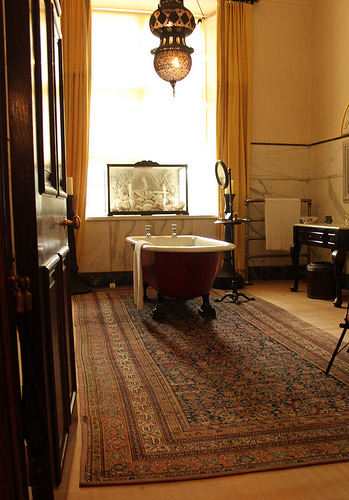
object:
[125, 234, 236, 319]
bathtub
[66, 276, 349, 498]
floor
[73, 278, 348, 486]
rug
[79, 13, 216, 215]
window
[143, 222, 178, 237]
two knobs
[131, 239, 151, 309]
towel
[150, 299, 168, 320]
feet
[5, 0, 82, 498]
door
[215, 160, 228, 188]
mirror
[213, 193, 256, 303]
stand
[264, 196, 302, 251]
towel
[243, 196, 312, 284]
rack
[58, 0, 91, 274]
curtain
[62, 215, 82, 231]
door knob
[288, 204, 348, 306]
table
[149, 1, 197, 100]
chandelier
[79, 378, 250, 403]
patterns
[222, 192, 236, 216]
candle stick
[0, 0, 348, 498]
bathroom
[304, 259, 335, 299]
garbage can